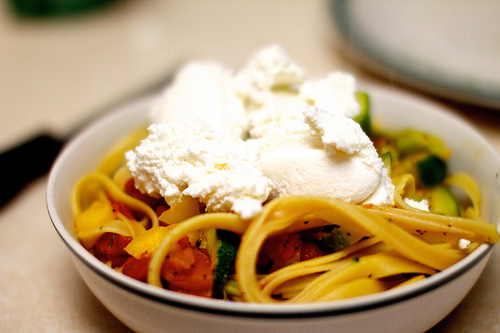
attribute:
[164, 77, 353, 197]
cheese — soft, ice cream, white, lumped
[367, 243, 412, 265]
pasta — food, yellow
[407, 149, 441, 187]
broccoli — pieced, green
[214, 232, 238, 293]
zucchini — green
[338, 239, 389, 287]
flecks — small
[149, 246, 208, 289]
tomato — chunked, red, chopped, cooked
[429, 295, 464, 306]
bowl — blue, white, striped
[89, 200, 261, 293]
vegetables — green, red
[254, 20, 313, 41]
background — blurry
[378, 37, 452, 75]
plate — blurred, white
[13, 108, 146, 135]
knife — blurred, black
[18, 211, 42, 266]
counter top — beige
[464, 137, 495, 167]
sauce — yellow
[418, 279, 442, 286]
stripe — blue